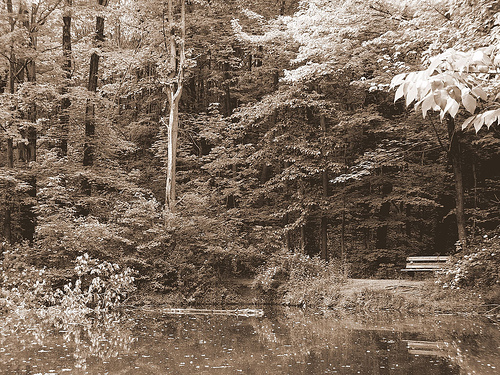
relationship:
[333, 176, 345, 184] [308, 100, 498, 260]
leaf on tree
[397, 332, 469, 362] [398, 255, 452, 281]
reflection of bench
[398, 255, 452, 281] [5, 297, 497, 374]
bench in water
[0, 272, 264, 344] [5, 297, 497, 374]
tree in water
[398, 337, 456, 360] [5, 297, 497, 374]
reflection in water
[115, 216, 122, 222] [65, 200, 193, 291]
leaf on tree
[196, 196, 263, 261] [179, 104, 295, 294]
leaf has tree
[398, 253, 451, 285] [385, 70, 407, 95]
bench in tree leaves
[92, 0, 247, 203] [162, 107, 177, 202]
tree has trunk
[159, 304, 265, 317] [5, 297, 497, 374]
log in water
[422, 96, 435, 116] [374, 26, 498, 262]
small leaf on tree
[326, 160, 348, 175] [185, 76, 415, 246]
small leaf on tree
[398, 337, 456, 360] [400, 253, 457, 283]
reflection of a bench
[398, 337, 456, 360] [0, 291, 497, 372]
reflection on water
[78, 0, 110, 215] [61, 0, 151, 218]
trunk of a tree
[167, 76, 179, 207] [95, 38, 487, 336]
trunk of a tree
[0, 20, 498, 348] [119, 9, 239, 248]
tree leaves on tree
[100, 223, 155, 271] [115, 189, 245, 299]
leaves on bush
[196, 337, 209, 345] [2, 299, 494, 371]
bubble on pond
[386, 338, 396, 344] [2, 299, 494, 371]
bubble on pond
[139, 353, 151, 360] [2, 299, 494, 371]
bubble on pond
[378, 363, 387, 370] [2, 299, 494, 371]
bubble on pond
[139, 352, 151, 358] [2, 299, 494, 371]
bubble on pond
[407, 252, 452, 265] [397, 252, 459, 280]
back on bench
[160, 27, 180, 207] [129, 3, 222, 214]
trunk of tree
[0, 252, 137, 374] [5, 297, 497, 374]
bush on water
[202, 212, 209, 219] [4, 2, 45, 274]
leaf on tree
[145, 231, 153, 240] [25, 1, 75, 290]
leaf on tree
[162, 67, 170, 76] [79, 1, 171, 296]
leaf on tree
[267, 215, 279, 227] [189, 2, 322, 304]
leaf on tree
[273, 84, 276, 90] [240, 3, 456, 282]
leaf on tree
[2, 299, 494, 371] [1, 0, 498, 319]
pond in woods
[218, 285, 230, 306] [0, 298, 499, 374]
person stands by pond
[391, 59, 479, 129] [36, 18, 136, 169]
leaves of tree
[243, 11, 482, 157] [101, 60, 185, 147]
leaves of tree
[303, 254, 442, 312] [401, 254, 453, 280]
area in front of bench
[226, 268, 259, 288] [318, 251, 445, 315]
path passing area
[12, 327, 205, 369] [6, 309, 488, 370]
leaves scattered over water